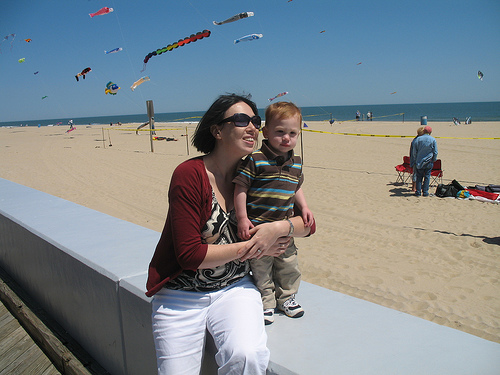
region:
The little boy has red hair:
[233, 102, 313, 323]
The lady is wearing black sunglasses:
[148, 90, 268, 373]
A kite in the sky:
[73, 65, 94, 84]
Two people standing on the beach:
[406, 125, 437, 199]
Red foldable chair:
[393, 154, 413, 185]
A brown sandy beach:
[3, 121, 496, 323]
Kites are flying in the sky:
[209, 8, 271, 45]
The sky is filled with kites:
[3, 5, 493, 108]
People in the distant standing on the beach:
[352, 108, 375, 123]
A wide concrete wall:
[0, 185, 499, 374]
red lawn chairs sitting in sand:
[394, 158, 442, 188]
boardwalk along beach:
[1, 280, 101, 371]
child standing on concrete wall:
[231, 100, 315, 322]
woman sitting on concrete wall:
[143, 94, 271, 374]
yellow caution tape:
[98, 125, 497, 145]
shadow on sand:
[411, 228, 499, 243]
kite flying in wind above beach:
[1, 7, 483, 100]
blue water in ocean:
[2, 100, 499, 126]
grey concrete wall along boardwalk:
[1, 179, 498, 374]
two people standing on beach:
[408, 128, 440, 198]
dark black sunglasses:
[215, 109, 265, 134]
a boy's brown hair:
[259, 95, 302, 131]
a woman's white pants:
[151, 285, 268, 373]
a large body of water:
[65, 100, 499, 122]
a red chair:
[395, 150, 415, 184]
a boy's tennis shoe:
[279, 293, 307, 318]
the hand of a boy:
[301, 208, 316, 234]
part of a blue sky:
[410, 0, 499, 28]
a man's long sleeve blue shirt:
[410, 132, 439, 169]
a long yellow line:
[303, 124, 410, 148]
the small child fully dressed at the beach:
[231, 98, 312, 324]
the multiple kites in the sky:
[1, 0, 496, 103]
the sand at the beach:
[1, 121, 499, 342]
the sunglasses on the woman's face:
[216, 113, 261, 127]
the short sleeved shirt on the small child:
[229, 138, 304, 233]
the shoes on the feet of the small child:
[261, 295, 304, 323]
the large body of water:
[0, 99, 499, 126]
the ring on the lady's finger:
[256, 247, 263, 254]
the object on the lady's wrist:
[285, 216, 294, 238]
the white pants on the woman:
[149, 275, 270, 373]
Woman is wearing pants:
[145, 275, 278, 373]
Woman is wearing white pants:
[144, 272, 273, 374]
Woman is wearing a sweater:
[145, 152, 215, 299]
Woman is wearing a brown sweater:
[144, 152, 215, 294]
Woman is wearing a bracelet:
[280, 208, 295, 242]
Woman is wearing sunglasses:
[207, 108, 266, 130]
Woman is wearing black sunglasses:
[203, 110, 263, 130]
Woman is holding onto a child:
[237, 99, 315, 330]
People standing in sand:
[407, 123, 436, 198]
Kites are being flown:
[2, 3, 485, 100]